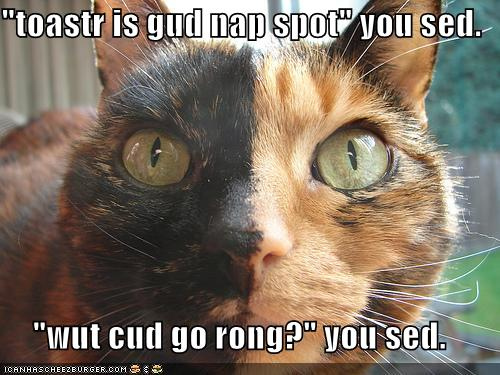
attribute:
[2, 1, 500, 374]
cat — orange white black, two faced, janus coloring, brown, black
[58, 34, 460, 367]
face — black, orange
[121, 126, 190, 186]
eye — large, green, yellow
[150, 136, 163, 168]
slit — black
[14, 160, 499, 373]
whiskers — white, long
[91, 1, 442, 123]
ears — pointy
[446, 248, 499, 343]
grass — green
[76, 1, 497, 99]
hairs — long, white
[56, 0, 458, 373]
head — calico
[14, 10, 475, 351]
words — misspelled, white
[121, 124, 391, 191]
eyes — green, parti-colored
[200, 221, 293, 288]
nose — pink, black, two-colored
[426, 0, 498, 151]
trees — green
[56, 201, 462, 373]
fur — orange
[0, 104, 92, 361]
back — orange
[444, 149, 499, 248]
fence — brown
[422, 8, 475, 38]
sed — misspelled